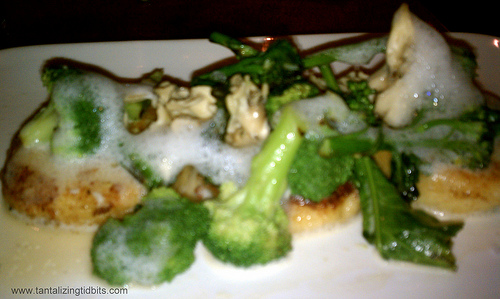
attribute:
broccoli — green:
[198, 122, 310, 297]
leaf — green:
[368, 196, 441, 250]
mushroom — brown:
[215, 83, 273, 132]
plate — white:
[32, 36, 492, 291]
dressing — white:
[375, 36, 450, 104]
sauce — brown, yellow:
[433, 171, 480, 181]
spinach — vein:
[325, 148, 427, 294]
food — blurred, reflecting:
[23, 178, 92, 260]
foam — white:
[161, 117, 219, 166]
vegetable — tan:
[172, 149, 207, 165]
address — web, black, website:
[0, 281, 150, 296]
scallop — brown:
[23, 131, 137, 217]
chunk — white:
[363, 17, 420, 68]